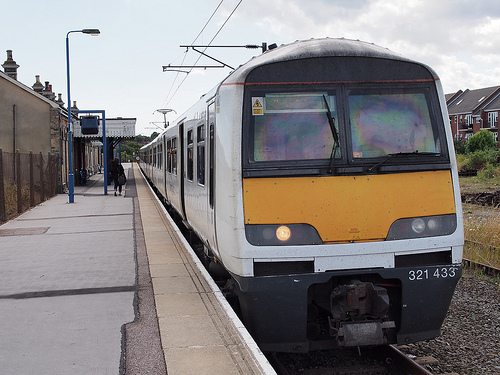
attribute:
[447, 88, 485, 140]
building — brick, apartment, nearby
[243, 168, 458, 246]
panel — yellow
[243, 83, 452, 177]
windshield — glass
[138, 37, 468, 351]
train — black, at the station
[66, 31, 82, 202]
pole — blue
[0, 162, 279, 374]
floor — concrete, dark, clean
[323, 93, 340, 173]
wiper — vertical, black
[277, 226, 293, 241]
light — round, on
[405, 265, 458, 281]
number — 321433, white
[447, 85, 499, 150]
house — brick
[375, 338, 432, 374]
rail — metal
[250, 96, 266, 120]
sticker — yellow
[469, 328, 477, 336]
gravel — gray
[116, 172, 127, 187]
bag — large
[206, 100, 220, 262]
door — closed